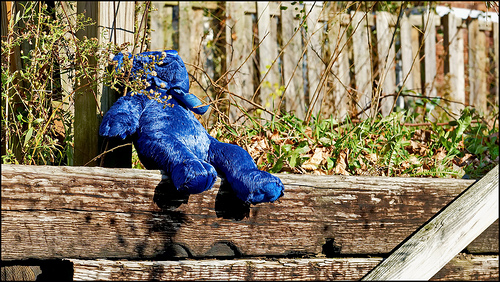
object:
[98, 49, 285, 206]
bear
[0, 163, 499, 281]
wood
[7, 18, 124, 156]
plant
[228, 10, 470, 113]
fence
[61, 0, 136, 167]
post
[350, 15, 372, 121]
beam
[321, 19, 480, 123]
railway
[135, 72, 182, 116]
elephant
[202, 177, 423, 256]
ledge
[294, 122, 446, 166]
grass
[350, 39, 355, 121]
hole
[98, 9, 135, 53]
stick